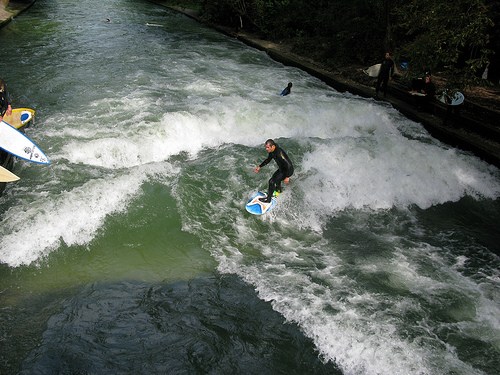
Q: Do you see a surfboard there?
A: Yes, there is a surfboard.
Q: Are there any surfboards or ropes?
A: Yes, there is a surfboard.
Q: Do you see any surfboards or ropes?
A: Yes, there is a surfboard.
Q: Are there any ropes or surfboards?
A: Yes, there is a surfboard.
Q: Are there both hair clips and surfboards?
A: No, there is a surfboard but no hair clips.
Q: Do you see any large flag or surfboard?
A: Yes, there is a large surfboard.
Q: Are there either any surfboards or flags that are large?
A: Yes, the surfboard is large.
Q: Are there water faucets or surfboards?
A: Yes, there is a water surfboard.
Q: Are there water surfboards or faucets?
A: Yes, there is a water surfboard.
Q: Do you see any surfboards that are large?
A: Yes, there is a large surfboard.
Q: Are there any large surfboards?
A: Yes, there is a large surfboard.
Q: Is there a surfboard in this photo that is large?
A: Yes, there is a surfboard that is large.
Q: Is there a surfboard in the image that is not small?
A: Yes, there is a large surfboard.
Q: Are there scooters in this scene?
A: No, there are no scooters.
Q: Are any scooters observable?
A: No, there are no scooters.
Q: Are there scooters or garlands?
A: No, there are no scooters or garlands.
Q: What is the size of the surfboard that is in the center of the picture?
A: The surfboard is large.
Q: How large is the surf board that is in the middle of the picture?
A: The surfboard is large.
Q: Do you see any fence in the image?
A: No, there are no fences.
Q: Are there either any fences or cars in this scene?
A: No, there are no fences or cars.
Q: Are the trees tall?
A: Yes, the trees are tall.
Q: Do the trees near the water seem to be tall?
A: Yes, the trees are tall.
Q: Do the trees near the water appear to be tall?
A: Yes, the trees are tall.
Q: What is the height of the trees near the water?
A: The trees are tall.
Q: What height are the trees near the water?
A: The trees are tall.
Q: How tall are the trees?
A: The trees are tall.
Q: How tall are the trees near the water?
A: The trees are tall.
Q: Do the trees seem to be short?
A: No, the trees are tall.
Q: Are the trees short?
A: No, the trees are tall.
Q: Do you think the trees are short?
A: No, the trees are tall.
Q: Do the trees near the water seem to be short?
A: No, the trees are tall.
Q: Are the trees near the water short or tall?
A: The trees are tall.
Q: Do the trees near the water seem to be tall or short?
A: The trees are tall.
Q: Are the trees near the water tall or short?
A: The trees are tall.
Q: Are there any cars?
A: No, there are no cars.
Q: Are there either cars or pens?
A: No, there are no cars or pens.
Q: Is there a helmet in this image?
A: No, there are no helmets.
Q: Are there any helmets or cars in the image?
A: No, there are no helmets or cars.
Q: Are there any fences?
A: No, there are no fences.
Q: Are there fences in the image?
A: No, there are no fences.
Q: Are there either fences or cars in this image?
A: No, there are no fences or cars.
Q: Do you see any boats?
A: Yes, there is a boat.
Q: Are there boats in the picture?
A: Yes, there is a boat.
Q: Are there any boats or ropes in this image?
A: Yes, there is a boat.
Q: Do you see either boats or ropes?
A: Yes, there is a boat.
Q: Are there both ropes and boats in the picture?
A: No, there is a boat but no ropes.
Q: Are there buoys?
A: No, there are no buoys.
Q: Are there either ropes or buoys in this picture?
A: No, there are no buoys or ropes.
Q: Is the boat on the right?
A: No, the boat is on the left of the image.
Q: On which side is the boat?
A: The boat is on the left of the image.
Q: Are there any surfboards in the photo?
A: Yes, there is a surfboard.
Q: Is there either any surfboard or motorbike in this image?
A: Yes, there is a surfboard.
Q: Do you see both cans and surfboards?
A: No, there is a surfboard but no cans.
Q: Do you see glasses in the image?
A: No, there are no glasses.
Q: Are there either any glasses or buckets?
A: No, there are no glasses or buckets.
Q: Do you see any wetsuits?
A: Yes, there is a wetsuit.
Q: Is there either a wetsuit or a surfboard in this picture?
A: Yes, there is a wetsuit.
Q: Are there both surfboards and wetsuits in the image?
A: Yes, there are both a wetsuit and a surfboard.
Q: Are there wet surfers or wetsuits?
A: Yes, there is a wet wetsuit.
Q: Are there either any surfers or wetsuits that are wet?
A: Yes, the wetsuit is wet.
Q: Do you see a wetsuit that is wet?
A: Yes, there is a wet wetsuit.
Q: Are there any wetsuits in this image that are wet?
A: Yes, there is a wetsuit that is wet.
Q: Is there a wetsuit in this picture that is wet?
A: Yes, there is a wetsuit that is wet.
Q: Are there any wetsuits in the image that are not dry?
A: Yes, there is a wet wetsuit.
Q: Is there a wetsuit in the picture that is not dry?
A: Yes, there is a wet wetsuit.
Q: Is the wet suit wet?
A: Yes, the wet suit is wet.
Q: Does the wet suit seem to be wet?
A: Yes, the wet suit is wet.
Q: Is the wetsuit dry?
A: No, the wetsuit is wet.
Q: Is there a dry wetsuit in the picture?
A: No, there is a wetsuit but it is wet.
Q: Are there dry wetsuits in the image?
A: No, there is a wetsuit but it is wet.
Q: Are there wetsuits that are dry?
A: No, there is a wetsuit but it is wet.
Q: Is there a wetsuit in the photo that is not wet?
A: No, there is a wetsuit but it is wet.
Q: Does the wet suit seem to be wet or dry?
A: The wet suit is wet.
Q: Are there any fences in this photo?
A: No, there are no fences.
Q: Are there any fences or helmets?
A: No, there are no fences or helmets.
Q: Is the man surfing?
A: Yes, the man is surfing.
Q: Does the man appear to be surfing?
A: Yes, the man is surfing.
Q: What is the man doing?
A: The man is surfing.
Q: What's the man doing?
A: The man is surfing.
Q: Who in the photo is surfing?
A: The man is surfing.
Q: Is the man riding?
A: No, the man is surfing.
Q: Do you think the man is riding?
A: No, the man is surfing.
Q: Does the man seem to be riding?
A: No, the man is surfing.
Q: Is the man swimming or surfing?
A: The man is surfing.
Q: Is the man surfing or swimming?
A: The man is surfing.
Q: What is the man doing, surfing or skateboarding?
A: The man is surfing.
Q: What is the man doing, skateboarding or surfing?
A: The man is surfing.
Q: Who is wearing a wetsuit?
A: The man is wearing a wetsuit.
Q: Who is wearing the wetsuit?
A: The man is wearing a wetsuit.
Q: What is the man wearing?
A: The man is wearing a wetsuit.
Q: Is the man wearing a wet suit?
A: Yes, the man is wearing a wet suit.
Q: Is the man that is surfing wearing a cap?
A: No, the man is wearing a wet suit.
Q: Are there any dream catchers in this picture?
A: No, there are no dream catchers.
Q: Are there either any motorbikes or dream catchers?
A: No, there are no dream catchers or motorbikes.